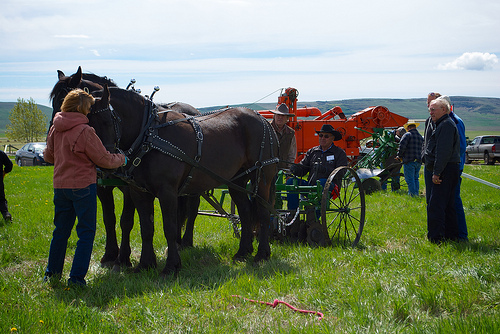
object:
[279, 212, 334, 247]
plow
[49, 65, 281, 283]
horses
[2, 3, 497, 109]
sky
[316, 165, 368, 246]
wheel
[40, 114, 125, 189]
jacket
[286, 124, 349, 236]
man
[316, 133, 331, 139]
glasses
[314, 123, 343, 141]
hat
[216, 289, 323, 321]
rope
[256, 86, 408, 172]
equipment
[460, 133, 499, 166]
truck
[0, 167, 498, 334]
field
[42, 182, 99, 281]
jeans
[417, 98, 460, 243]
people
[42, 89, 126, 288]
woman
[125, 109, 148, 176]
harness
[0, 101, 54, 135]
mountain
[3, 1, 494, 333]
background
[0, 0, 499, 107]
cloud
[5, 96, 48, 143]
trees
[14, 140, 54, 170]
cars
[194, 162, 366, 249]
contraption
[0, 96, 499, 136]
hills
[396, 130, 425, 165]
shirt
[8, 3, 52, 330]
left